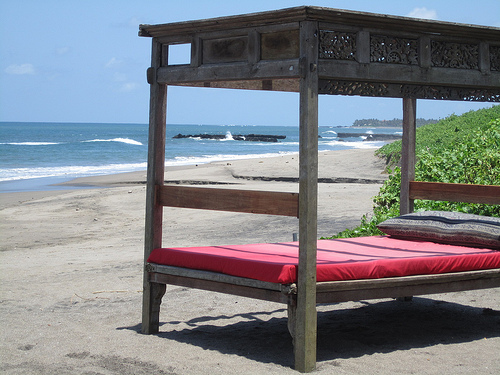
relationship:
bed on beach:
[138, 7, 499, 373] [4, 147, 497, 374]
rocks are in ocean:
[170, 131, 292, 144] [3, 122, 427, 186]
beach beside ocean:
[4, 147, 497, 374] [3, 122, 427, 186]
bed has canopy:
[138, 7, 499, 373] [145, 6, 499, 99]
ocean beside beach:
[3, 122, 427, 186] [4, 147, 497, 374]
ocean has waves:
[3, 122, 427, 186] [222, 127, 242, 148]